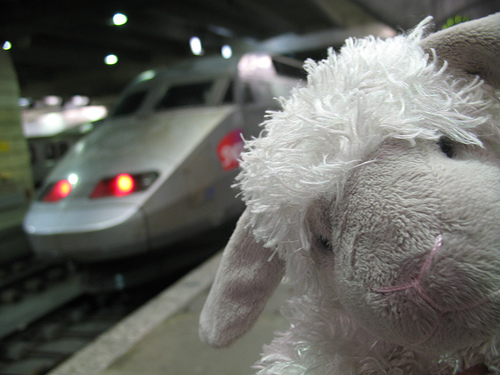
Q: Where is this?
A: This is at the train station.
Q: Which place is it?
A: It is a train station.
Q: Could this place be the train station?
A: Yes, it is the train station.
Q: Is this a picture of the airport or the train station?
A: It is showing the train station.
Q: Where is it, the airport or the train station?
A: It is the train station.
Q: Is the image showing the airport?
A: No, the picture is showing the train station.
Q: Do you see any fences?
A: No, there are no fences.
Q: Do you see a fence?
A: No, there are no fences.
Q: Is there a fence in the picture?
A: No, there are no fences.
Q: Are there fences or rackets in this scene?
A: No, there are no fences or rackets.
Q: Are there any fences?
A: No, there are no fences.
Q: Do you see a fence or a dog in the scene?
A: No, there are no fences or dogs.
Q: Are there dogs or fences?
A: No, there are no fences or dogs.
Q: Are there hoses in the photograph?
A: No, there are no hoses.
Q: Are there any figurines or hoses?
A: No, there are no hoses or figurines.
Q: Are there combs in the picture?
A: No, there are no combs.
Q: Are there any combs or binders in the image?
A: No, there are no combs or binders.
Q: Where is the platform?
A: The platform is at the train station.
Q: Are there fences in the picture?
A: No, there are no fences.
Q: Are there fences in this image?
A: No, there are no fences.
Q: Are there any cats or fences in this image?
A: No, there are no fences or cats.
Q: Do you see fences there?
A: No, there are no fences.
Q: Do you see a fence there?
A: No, there are no fences.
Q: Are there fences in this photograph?
A: No, there are no fences.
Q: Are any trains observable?
A: Yes, there is a train.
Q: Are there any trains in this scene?
A: Yes, there is a train.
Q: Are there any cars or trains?
A: Yes, there is a train.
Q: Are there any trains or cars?
A: Yes, there is a train.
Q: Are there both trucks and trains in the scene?
A: No, there is a train but no trucks.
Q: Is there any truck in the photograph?
A: No, there are no trucks.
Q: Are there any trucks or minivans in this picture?
A: No, there are no trucks or minivans.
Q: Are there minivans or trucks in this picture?
A: No, there are no trucks or minivans.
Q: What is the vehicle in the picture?
A: The vehicle is a train.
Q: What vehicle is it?
A: The vehicle is a train.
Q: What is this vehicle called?
A: That is a train.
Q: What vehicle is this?
A: That is a train.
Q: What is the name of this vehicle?
A: That is a train.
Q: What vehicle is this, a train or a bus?
A: That is a train.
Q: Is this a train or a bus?
A: This is a train.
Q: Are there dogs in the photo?
A: No, there are no dogs.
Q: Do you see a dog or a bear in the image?
A: No, there are no dogs or bears.